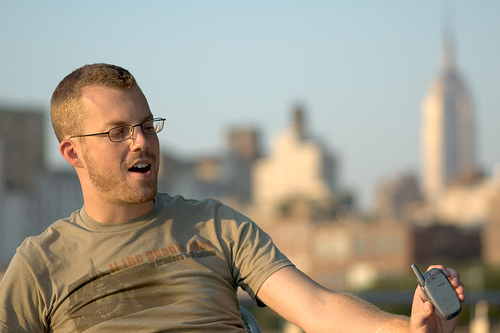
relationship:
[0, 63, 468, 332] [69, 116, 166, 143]
guy wearing glasses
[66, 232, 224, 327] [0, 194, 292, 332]
logo on shirt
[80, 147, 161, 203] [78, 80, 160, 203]
beards on face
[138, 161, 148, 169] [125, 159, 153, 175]
teeth in mouth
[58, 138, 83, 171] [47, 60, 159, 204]
ear on head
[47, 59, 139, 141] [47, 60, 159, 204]
hair on head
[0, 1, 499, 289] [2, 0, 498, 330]
city in background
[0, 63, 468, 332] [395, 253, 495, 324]
guy holding phone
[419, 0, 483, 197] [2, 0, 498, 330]
building in background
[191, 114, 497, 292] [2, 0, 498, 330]
cityscape in background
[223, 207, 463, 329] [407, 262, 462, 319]
arm holding cellphone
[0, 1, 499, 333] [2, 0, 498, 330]
city in background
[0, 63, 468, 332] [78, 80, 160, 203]
guy has face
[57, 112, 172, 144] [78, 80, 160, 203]
glasses on face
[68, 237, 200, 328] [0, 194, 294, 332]
image on shirt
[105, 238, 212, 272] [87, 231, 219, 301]
words on shirt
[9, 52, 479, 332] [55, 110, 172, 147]
guy wears glasses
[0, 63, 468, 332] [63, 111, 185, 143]
guy wearing glasses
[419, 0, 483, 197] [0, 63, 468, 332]
building behind guy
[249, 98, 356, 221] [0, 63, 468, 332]
building behind guy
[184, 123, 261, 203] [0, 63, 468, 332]
building behind guy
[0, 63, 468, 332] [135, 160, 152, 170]
guy has teeth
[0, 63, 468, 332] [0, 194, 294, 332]
guy wears shirt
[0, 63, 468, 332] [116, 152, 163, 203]
guy has beards